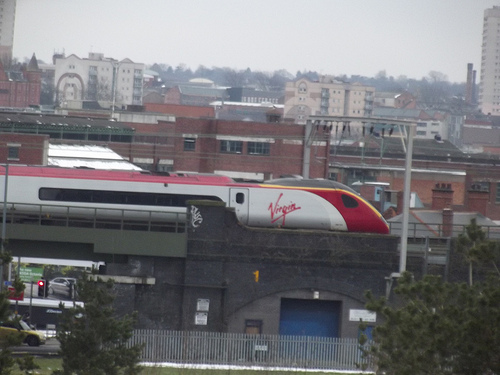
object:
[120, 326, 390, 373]
fence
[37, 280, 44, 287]
light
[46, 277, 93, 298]
car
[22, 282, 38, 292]
road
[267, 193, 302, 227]
brand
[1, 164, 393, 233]
train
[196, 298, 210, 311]
sign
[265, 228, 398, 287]
wall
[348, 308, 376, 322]
sign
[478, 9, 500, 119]
building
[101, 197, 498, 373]
building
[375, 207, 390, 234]
nose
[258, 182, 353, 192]
stripe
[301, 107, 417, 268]
metal scaffolding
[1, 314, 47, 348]
car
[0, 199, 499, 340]
bridge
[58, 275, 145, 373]
tree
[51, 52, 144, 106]
building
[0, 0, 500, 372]
city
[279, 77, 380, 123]
building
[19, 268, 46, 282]
sign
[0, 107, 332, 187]
building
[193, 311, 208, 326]
signs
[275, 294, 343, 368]
doors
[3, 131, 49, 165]
buildings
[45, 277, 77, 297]
silver car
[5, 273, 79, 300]
parking lot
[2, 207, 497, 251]
track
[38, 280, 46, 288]
signal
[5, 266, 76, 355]
intersection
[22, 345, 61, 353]
road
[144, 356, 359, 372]
sidewalk